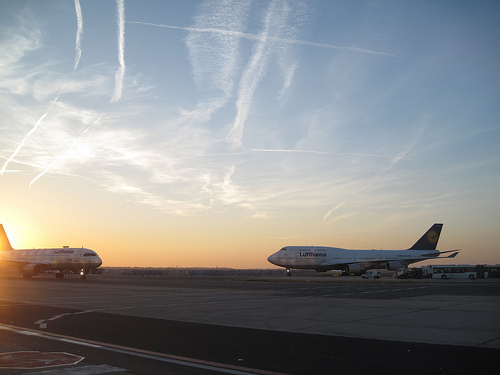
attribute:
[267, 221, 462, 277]
airliner — idle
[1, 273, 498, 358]
cement — black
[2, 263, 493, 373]
runway — grey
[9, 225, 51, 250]
light — bright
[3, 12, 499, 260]
sky — orange, blue, orange and blue, yellow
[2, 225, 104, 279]
airplane — white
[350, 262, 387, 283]
vehicle — white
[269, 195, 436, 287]
airplane — white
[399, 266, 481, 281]
shuttle — bus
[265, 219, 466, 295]
airplane — large, white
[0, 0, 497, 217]
sky — orange, blue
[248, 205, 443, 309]
plane — muted-grey, yellow, patterned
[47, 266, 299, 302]
lights — small, white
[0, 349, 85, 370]
symbol — red, white, painted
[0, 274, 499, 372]
paved ground — airport, striped, symboled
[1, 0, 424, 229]
smoke — jet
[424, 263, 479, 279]
bus — large, white, transit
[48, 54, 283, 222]
clouds — streaky, puffy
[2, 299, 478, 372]
cement — black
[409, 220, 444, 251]
tail — dark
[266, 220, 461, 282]
plane — light-colored